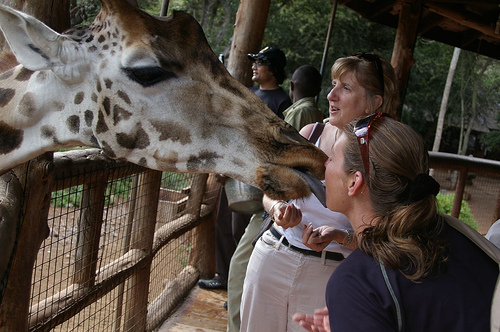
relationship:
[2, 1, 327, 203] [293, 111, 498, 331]
giraffe licking lady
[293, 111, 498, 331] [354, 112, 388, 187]
lady has sunglasses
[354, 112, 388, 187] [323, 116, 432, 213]
sunglasses on head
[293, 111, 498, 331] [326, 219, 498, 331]
lady wearing shirt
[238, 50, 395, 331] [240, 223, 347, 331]
lady wearing pants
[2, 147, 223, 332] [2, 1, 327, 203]
fence separating giraffe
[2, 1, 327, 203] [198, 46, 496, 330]
giraffe separated from people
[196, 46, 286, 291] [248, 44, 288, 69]
man wearing cap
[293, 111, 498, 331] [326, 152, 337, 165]
lady with eyes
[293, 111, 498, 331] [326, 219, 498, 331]
lady with shirt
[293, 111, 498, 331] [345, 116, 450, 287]
lady with hair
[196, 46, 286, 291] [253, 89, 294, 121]
man with shirt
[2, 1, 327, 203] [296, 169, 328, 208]
giraffe sticking out tongue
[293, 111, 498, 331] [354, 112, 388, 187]
lady with sunglasses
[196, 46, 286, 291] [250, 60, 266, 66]
man with glasses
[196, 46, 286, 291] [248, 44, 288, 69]
man with cap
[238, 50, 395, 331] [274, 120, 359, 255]
lady with tank top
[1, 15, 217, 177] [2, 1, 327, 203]
spots on giraffe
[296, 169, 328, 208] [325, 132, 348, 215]
tongue touching face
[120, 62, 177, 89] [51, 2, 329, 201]
eye on head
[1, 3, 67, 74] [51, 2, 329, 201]
ear on head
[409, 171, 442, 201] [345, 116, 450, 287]
scrunchie in hair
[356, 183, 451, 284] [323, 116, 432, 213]
ponytail on head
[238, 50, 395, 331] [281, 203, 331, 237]
lady holding feed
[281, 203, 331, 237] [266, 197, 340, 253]
feed in hands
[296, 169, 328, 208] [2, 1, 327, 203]
tongue of giraffe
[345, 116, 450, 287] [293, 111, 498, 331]
hair of lady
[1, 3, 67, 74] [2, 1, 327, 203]
ear of giraffe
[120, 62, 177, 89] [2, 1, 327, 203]
eye of giraffe